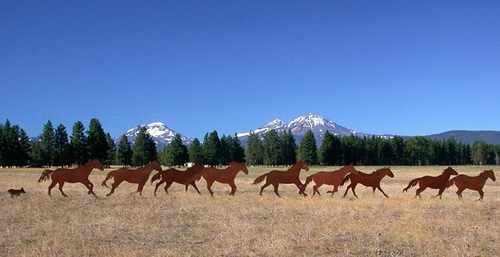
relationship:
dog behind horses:
[6, 187, 27, 198] [38, 159, 496, 199]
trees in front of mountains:
[0, 119, 500, 169] [18, 113, 500, 149]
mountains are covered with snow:
[18, 113, 500, 149] [18, 112, 395, 153]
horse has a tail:
[38, 158, 104, 199] [36, 170, 54, 183]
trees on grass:
[0, 119, 500, 169] [0, 163, 500, 256]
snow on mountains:
[18, 112, 395, 153] [18, 113, 500, 149]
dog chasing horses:
[6, 187, 27, 198] [38, 159, 496, 199]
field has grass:
[0, 117, 499, 256] [0, 163, 500, 256]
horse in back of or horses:
[38, 158, 104, 199] [38, 159, 496, 199]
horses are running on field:
[38, 159, 496, 199] [0, 117, 499, 256]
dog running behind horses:
[6, 187, 27, 198] [38, 159, 496, 199]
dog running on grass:
[6, 187, 27, 198] [0, 163, 500, 256]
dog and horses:
[6, 187, 27, 198] [38, 159, 496, 199]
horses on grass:
[38, 159, 496, 199] [0, 163, 500, 256]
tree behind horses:
[189, 137, 204, 166] [38, 159, 496, 199]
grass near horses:
[0, 163, 500, 256] [38, 159, 496, 199]